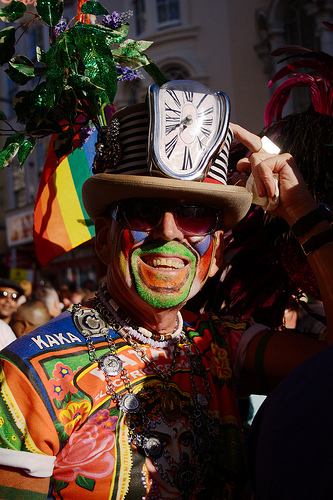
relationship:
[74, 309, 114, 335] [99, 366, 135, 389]
bottlecap on chain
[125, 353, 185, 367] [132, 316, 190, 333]
necklace around neck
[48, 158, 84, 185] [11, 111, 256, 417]
flag behind man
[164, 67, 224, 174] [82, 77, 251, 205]
clock on hat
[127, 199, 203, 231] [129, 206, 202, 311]
sunglasses on face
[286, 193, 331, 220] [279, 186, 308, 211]
watch on wrist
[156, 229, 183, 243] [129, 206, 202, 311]
nose of face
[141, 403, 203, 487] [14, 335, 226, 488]
woman on shirt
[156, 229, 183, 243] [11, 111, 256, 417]
nose of man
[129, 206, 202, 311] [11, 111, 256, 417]
face of man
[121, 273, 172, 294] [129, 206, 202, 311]
makeup on face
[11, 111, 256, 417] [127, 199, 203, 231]
man wearing sunglasses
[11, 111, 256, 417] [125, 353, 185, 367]
man wearing necklace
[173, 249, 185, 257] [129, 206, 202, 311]
paint on face